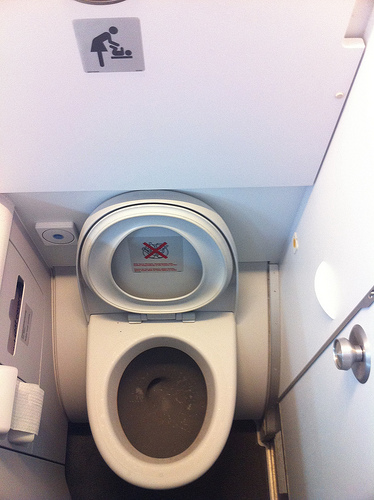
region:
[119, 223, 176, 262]
an x red sign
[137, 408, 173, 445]
dirt in the toilet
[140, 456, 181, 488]
white edge of the toilet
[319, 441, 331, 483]
white part of the day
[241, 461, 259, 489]
part of a black mat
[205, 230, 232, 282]
an edge of the toilet's lid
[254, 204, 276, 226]
part of a white wall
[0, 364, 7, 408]
part of the white tissue handle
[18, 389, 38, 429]
part of a white tissue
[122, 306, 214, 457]
a black dirty toilet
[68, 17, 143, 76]
Symbol of a woman changing a baby's diaper.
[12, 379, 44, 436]
White toilet paper roll.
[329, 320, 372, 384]
Silver circular knob on door.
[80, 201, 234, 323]
White toilet lid in up position.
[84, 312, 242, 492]
White toilet bowl seat.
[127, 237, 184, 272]
Warning sign with red 'X'.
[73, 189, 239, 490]
Toilet in a confined space.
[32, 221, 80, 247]
Square white wall mounted sensor.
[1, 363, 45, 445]
White toilet paper rack.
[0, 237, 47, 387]
Slot for toilet paper covers.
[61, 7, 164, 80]
Sign above toilet.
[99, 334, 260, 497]
Inside of toilet bowl.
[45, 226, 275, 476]
Toilet in an airplane.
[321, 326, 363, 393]
Metal door knob on door.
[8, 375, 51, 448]
White toilet paper on wall.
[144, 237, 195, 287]
Sign with red X.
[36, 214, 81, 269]
Button that flushes toilet.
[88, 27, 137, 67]
Woman figure on sign.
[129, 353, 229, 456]
Gray inside of bowl.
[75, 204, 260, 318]
Toilet lid open.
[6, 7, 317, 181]
pullout table for infants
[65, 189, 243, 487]
white airline toilet with gray interior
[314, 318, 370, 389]
silver metal door handle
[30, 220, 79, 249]
blue and white button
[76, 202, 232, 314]
white raised toilet seat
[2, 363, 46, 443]
roll of white toilet paper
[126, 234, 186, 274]
white sign with red lettering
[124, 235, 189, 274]
white sign with black graphic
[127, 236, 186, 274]
white sign with red x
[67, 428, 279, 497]
speckled grey floor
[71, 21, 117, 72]
Sign of black stick figure woman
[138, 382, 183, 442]
Inside of toilet bowl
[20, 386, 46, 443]
White roll of toilet paper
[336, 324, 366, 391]
Silver door knob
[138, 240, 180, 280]
Warning of self flushing sign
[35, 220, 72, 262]
Toilet flusher with blue button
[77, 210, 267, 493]
White toilet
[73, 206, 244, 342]
Open toilet lid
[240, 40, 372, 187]
White plastic wall behind toilet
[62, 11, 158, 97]
Diaper changing sign on wall